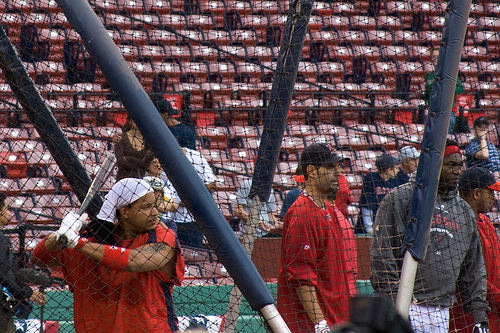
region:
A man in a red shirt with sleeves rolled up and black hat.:
[280, 140, 355, 331]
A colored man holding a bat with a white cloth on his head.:
[30, 178, 184, 332]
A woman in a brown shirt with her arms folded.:
[111, 114, 151, 181]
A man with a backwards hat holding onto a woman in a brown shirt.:
[150, 97, 198, 151]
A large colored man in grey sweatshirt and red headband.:
[371, 140, 491, 331]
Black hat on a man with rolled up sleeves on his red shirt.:
[298, 140, 350, 165]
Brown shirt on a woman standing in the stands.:
[115, 132, 150, 180]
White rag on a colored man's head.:
[95, 174, 155, 221]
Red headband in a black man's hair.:
[438, 140, 459, 157]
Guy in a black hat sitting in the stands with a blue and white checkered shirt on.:
[461, 116, 498, 168]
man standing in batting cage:
[28, 149, 185, 331]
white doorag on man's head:
[95, 169, 154, 225]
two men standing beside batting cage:
[292, 140, 482, 331]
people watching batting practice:
[112, 96, 499, 228]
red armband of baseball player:
[98, 239, 126, 270]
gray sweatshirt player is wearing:
[375, 176, 493, 311]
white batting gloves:
[60, 212, 77, 244]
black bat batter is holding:
[55, 149, 115, 246]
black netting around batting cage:
[12, 46, 492, 326]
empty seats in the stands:
[6, 53, 487, 227]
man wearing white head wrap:
[36, 145, 183, 323]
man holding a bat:
[35, 152, 176, 329]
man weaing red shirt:
[21, 146, 213, 328]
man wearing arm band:
[26, 155, 181, 330]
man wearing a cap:
[280, 137, 356, 287]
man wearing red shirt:
[285, 135, 343, 318]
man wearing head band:
[438, 138, 463, 309]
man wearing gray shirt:
[445, 137, 485, 308]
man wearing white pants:
[430, 140, 466, 322]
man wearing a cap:
[467, 163, 498, 207]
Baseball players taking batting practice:
[6, 5, 496, 327]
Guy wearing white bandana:
[98, 176, 161, 230]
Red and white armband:
[98, 242, 134, 271]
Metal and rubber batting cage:
[7, 76, 492, 323]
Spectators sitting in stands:
[1, 132, 498, 222]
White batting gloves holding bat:
[51, 205, 85, 250]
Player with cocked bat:
[36, 170, 200, 330]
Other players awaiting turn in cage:
[275, 134, 498, 326]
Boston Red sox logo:
[421, 206, 464, 253]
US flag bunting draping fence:
[167, 309, 227, 331]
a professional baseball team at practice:
[11, 4, 488, 299]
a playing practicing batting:
[36, 139, 193, 331]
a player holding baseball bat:
[32, 141, 193, 331]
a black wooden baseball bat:
[77, 145, 117, 257]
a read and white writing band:
[97, 240, 128, 271]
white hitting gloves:
[52, 208, 87, 252]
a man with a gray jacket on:
[374, 141, 493, 321]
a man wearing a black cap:
[296, 137, 355, 192]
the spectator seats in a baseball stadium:
[5, 0, 497, 105]